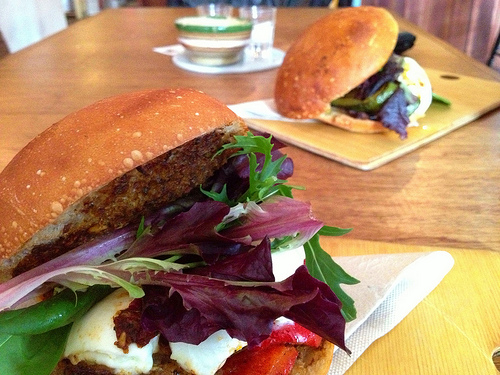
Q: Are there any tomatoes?
A: Yes, there is a tomato.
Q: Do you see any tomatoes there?
A: Yes, there is a tomato.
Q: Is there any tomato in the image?
A: Yes, there is a tomato.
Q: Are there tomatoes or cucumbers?
A: Yes, there is a tomato.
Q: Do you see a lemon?
A: No, there are no lemons.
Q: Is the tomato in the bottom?
A: Yes, the tomato is in the bottom of the image.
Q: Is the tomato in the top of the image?
A: No, the tomato is in the bottom of the image.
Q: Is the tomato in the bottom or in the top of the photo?
A: The tomato is in the bottom of the image.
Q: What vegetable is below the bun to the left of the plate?
A: The vegetable is a tomato.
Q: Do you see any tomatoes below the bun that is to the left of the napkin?
A: Yes, there is a tomato below the bun.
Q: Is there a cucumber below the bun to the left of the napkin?
A: No, there is a tomato below the bun.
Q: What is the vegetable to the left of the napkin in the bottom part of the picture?
A: The vegetable is a tomato.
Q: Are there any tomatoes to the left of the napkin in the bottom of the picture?
A: Yes, there is a tomato to the left of the napkin.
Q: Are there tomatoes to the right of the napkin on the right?
A: No, the tomato is to the left of the napkin.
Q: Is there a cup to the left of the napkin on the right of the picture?
A: No, there is a tomato to the left of the napkin.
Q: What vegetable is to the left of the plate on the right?
A: The vegetable is a tomato.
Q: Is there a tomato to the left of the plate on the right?
A: Yes, there is a tomato to the left of the plate.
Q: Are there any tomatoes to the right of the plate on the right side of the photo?
A: No, the tomato is to the left of the plate.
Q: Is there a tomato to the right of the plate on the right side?
A: No, the tomato is to the left of the plate.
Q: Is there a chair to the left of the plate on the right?
A: No, there is a tomato to the left of the plate.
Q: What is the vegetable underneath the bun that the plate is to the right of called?
A: The vegetable is a tomato.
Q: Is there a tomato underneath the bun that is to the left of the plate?
A: Yes, there is a tomato underneath the bun.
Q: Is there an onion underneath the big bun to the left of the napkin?
A: No, there is a tomato underneath the bun.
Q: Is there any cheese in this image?
A: Yes, there is cheese.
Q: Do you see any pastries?
A: No, there are no pastries.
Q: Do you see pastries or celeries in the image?
A: No, there are no pastries or celeries.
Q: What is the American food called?
A: The food is cheese.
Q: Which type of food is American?
A: The food is cheese.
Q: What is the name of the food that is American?
A: The food is cheese.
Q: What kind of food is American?
A: The food is cheese.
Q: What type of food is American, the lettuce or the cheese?
A: The cheese is american.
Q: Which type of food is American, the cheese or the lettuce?
A: The cheese is american.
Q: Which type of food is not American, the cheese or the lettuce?
A: The lettuce is not american.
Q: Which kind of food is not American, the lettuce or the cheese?
A: The lettuce is not american.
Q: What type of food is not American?
A: The food is lettuce.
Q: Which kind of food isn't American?
A: The food is lettuce.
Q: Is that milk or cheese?
A: That is cheese.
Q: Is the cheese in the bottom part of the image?
A: Yes, the cheese is in the bottom of the image.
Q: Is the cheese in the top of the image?
A: No, the cheese is in the bottom of the image.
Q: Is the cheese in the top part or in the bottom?
A: The cheese is in the bottom of the image.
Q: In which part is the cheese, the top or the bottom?
A: The cheese is in the bottom of the image.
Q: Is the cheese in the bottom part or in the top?
A: The cheese is in the bottom of the image.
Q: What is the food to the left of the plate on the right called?
A: The food is cheese.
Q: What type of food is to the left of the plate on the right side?
A: The food is cheese.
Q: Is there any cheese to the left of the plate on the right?
A: Yes, there is cheese to the left of the plate.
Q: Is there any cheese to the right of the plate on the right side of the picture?
A: No, the cheese is to the left of the plate.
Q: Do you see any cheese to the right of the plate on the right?
A: No, the cheese is to the left of the plate.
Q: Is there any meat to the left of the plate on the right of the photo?
A: No, there is cheese to the left of the plate.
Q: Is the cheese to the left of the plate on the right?
A: Yes, the cheese is to the left of the plate.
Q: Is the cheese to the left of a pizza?
A: No, the cheese is to the left of the plate.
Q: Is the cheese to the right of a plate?
A: No, the cheese is to the left of a plate.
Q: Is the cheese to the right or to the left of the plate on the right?
A: The cheese is to the left of the plate.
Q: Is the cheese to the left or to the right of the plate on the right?
A: The cheese is to the left of the plate.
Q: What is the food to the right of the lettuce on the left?
A: The food is cheese.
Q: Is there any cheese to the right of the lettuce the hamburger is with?
A: Yes, there is cheese to the right of the lettuce.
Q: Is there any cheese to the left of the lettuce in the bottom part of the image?
A: No, the cheese is to the right of the lettuce.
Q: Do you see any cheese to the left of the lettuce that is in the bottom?
A: No, the cheese is to the right of the lettuce.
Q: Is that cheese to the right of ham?
A: No, the cheese is to the right of the lettuce.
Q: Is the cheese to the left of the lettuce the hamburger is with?
A: No, the cheese is to the right of the lettuce.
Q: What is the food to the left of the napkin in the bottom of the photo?
A: The food is cheese.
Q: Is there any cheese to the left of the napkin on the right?
A: Yes, there is cheese to the left of the napkin.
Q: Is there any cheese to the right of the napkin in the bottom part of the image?
A: No, the cheese is to the left of the napkin.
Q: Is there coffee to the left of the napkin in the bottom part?
A: No, there is cheese to the left of the napkin.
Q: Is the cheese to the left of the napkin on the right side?
A: Yes, the cheese is to the left of the napkin.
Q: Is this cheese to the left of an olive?
A: No, the cheese is to the left of the napkin.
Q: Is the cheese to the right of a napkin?
A: No, the cheese is to the left of a napkin.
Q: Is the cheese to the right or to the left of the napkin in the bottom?
A: The cheese is to the left of the napkin.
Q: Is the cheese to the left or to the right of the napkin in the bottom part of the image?
A: The cheese is to the left of the napkin.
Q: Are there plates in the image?
A: Yes, there is a plate.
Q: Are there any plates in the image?
A: Yes, there is a plate.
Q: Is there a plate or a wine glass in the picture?
A: Yes, there is a plate.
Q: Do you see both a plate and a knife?
A: No, there is a plate but no knives.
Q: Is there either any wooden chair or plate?
A: Yes, there is a wood plate.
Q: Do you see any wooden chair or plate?
A: Yes, there is a wood plate.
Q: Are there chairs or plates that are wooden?
A: Yes, the plate is wooden.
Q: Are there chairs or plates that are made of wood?
A: Yes, the plate is made of wood.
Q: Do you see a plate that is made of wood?
A: Yes, there is a plate that is made of wood.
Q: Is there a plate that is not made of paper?
A: Yes, there is a plate that is made of wood.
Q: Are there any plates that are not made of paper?
A: Yes, there is a plate that is made of wood.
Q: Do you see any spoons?
A: No, there are no spoons.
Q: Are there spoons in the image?
A: No, there are no spoons.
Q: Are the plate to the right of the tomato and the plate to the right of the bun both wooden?
A: Yes, both the plate and the plate are wooden.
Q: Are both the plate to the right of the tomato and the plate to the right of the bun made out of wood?
A: Yes, both the plate and the plate are made of wood.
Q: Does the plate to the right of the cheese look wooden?
A: Yes, the plate is wooden.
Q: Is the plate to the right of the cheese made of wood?
A: Yes, the plate is made of wood.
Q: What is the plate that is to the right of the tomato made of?
A: The plate is made of wood.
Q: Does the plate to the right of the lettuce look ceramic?
A: No, the plate is wooden.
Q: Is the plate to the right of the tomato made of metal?
A: No, the plate is made of wood.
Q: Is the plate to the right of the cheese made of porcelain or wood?
A: The plate is made of wood.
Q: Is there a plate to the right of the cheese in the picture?
A: Yes, there is a plate to the right of the cheese.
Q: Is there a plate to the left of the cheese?
A: No, the plate is to the right of the cheese.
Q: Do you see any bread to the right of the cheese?
A: No, there is a plate to the right of the cheese.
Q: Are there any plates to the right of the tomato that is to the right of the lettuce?
A: Yes, there is a plate to the right of the tomato.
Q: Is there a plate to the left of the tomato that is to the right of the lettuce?
A: No, the plate is to the right of the tomato.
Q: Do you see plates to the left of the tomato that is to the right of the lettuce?
A: No, the plate is to the right of the tomato.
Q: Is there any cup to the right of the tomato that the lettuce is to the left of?
A: No, there is a plate to the right of the tomato.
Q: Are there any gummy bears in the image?
A: No, there are no gummy bears.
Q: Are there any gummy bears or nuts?
A: No, there are no gummy bears or nuts.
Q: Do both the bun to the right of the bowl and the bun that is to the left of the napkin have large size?
A: Yes, both the bun and the bun are large.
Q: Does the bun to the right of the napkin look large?
A: Yes, the bun is large.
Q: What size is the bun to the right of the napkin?
A: The bun is large.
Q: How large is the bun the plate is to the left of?
A: The bun is large.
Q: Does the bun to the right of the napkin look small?
A: No, the bun is large.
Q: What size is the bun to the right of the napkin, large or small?
A: The bun is large.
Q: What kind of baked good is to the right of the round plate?
A: The food is a bun.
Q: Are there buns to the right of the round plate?
A: Yes, there is a bun to the right of the plate.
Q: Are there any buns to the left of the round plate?
A: No, the bun is to the right of the plate.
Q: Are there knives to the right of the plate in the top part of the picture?
A: No, there is a bun to the right of the plate.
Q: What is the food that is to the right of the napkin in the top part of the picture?
A: The food is a bun.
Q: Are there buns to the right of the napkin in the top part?
A: Yes, there is a bun to the right of the napkin.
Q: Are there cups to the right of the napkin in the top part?
A: No, there is a bun to the right of the napkin.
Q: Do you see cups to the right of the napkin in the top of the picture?
A: No, there is a bun to the right of the napkin.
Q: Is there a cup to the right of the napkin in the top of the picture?
A: No, there is a bun to the right of the napkin.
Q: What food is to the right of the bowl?
A: The food is a bun.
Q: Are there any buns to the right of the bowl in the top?
A: Yes, there is a bun to the right of the bowl.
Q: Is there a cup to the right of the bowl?
A: No, there is a bun to the right of the bowl.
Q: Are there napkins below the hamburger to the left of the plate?
A: Yes, there is a napkin below the hamburger.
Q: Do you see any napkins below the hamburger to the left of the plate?
A: Yes, there is a napkin below the hamburger.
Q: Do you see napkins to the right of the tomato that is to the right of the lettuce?
A: Yes, there is a napkin to the right of the tomato.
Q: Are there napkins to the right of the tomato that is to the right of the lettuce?
A: Yes, there is a napkin to the right of the tomato.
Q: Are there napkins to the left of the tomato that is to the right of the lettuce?
A: No, the napkin is to the right of the tomato.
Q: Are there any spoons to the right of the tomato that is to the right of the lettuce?
A: No, there is a napkin to the right of the tomato.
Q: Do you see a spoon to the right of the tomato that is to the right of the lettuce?
A: No, there is a napkin to the right of the tomato.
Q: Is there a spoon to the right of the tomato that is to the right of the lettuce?
A: No, there is a napkin to the right of the tomato.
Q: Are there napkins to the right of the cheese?
A: Yes, there is a napkin to the right of the cheese.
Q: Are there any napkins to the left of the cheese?
A: No, the napkin is to the right of the cheese.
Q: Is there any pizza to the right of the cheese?
A: No, there is a napkin to the right of the cheese.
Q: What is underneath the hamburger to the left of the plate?
A: The napkin is underneath the hamburger.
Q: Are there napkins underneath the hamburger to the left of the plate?
A: Yes, there is a napkin underneath the hamburger.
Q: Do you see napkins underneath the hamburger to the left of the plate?
A: Yes, there is a napkin underneath the hamburger.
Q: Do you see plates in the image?
A: Yes, there is a plate.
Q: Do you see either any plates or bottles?
A: Yes, there is a plate.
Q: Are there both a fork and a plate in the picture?
A: No, there is a plate but no forks.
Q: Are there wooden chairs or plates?
A: Yes, there is a wood plate.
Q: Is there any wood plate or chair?
A: Yes, there is a wood plate.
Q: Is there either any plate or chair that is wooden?
A: Yes, the plate is wooden.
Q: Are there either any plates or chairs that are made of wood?
A: Yes, the plate is made of wood.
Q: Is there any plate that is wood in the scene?
A: Yes, there is a wood plate.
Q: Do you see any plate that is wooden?
A: Yes, there is a plate that is wooden.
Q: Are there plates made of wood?
A: Yes, there is a plate that is made of wood.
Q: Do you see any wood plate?
A: Yes, there is a plate that is made of wood.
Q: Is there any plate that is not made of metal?
A: Yes, there is a plate that is made of wood.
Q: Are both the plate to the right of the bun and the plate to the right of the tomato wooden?
A: Yes, both the plate and the plate are wooden.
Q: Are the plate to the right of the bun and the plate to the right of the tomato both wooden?
A: Yes, both the plate and the plate are wooden.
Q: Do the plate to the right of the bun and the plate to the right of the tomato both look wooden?
A: Yes, both the plate and the plate are wooden.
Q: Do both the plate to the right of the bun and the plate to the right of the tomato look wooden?
A: Yes, both the plate and the plate are wooden.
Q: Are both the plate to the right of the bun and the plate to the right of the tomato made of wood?
A: Yes, both the plate and the plate are made of wood.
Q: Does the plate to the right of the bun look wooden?
A: Yes, the plate is wooden.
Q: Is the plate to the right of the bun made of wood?
A: Yes, the plate is made of wood.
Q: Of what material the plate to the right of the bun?
A: The plate is made of wood.